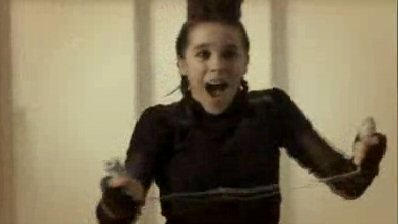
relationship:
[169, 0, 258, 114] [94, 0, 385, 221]
head of girl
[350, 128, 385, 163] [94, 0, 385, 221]
hand of girl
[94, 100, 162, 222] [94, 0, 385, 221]
arm of girl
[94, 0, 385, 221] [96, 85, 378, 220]
girl wearing shirt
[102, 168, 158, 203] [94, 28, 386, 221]
hand of girl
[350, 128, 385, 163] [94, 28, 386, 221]
hand of girl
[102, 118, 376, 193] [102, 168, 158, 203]
string between hand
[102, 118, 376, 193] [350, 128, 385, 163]
string between hand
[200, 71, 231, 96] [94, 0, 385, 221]
mouth of girl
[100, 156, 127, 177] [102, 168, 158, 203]
pole in hand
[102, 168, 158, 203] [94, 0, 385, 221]
hand of girl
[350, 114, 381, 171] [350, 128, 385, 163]
pole in hand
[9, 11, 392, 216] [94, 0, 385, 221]
wall behind girl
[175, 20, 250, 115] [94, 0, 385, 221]
face of girl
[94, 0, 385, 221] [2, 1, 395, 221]
girl in room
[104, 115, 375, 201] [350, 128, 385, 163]
wii remote in hand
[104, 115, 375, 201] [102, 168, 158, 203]
wii remote in hand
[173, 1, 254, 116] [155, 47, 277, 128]
hair in pig tails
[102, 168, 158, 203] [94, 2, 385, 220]
hand of woman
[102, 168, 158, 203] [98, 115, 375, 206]
hand with wii controller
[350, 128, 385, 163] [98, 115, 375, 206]
hand with wii controller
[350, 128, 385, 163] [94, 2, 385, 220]
hand of woman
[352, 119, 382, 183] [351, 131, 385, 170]
controller in hand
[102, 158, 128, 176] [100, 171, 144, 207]
controller in hand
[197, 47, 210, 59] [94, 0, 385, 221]
eye of girl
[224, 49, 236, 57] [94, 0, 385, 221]
eye of girl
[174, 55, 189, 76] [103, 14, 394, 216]
ear of girl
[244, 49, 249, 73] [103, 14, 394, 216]
ear of girl